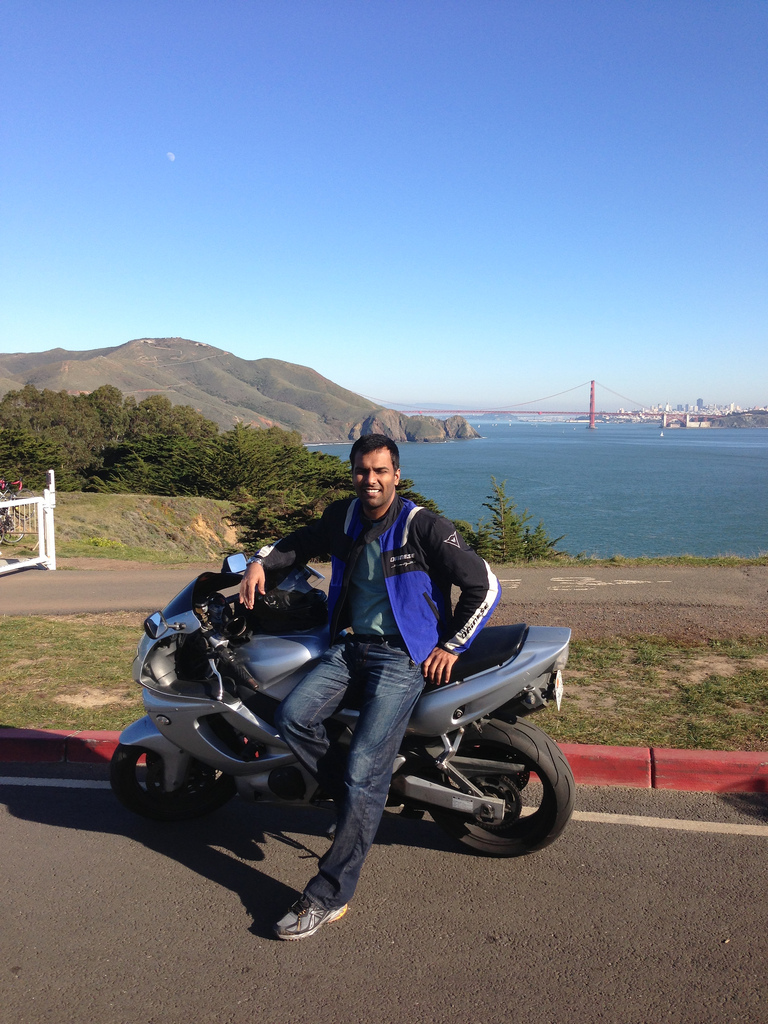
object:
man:
[243, 434, 499, 941]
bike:
[112, 552, 576, 859]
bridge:
[394, 381, 711, 429]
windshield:
[161, 572, 243, 635]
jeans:
[274, 638, 430, 909]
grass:
[605, 650, 736, 721]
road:
[0, 752, 768, 1024]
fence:
[0, 497, 44, 573]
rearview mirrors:
[228, 553, 246, 573]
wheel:
[431, 718, 576, 857]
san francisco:
[616, 398, 765, 414]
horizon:
[410, 410, 759, 423]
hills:
[0, 336, 482, 445]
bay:
[299, 417, 768, 561]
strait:
[306, 438, 489, 463]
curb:
[574, 745, 764, 795]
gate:
[5, 470, 57, 573]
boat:
[660, 431, 665, 437]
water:
[566, 462, 698, 538]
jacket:
[253, 496, 502, 656]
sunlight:
[342, 148, 743, 358]